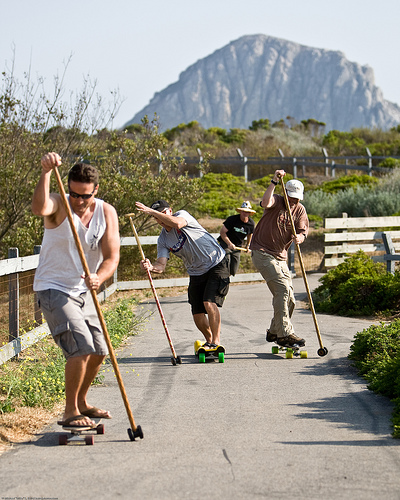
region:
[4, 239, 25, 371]
A wooden fence post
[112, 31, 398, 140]
A mountain in the background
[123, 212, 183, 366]
A wooden push pole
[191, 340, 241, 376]
A skateboard with green wheels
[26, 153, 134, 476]
A man wearing flip flops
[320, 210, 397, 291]
A wooden fence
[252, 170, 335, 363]
A man on a skateboard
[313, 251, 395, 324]
A green bush in a park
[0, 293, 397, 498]
An asphalt skating path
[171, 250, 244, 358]
A pair of brown cargo shorts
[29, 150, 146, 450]
a man skateboarding with a pole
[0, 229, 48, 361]
a small wooden fence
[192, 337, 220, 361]
a skateboard with colorful wheels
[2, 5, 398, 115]
a pristine gray sky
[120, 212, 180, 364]
a pole with wheels used to propel a skateboard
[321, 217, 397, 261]
a wooden barricade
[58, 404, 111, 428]
a man's flipflops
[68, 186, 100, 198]
a man's sunglasses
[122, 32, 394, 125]
a rocky mountain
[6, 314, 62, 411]
wild flowers growing on the dirt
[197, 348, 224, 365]
green skate board wheels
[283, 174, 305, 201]
white hat on head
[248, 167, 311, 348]
man with black watch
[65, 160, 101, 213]
sunglasses on mans face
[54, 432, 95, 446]
red skate board wheels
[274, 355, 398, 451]
shadows from green shrubs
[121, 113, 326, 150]
tall trees in background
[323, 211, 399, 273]
fence made of wood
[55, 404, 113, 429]
sandals on mans feet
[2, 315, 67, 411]
yellow flowers near path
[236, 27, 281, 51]
curved top of large mountain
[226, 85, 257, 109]
curves in large white mountain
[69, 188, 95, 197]
wrap a round sun glasses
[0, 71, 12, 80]
single leaf on branch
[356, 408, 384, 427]
indent in white sidewalk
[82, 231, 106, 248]
black logo on white tee shirt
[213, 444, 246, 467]
black spot in road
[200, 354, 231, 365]
green wheels on skateboard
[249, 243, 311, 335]
man wearing tan pants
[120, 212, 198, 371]
large stick in man's hand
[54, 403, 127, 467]
Skateboard on a paved path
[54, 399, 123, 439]
Sandals worn by a skateboarder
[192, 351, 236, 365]
Bright green wheels on a skateboard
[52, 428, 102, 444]
Red wheels on a skateboard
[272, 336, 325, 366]
Yellow wheels on a skateboard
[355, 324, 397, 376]
Bushes on the side of a paved path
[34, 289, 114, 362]
Gray shorts on a skateboarder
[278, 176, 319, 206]
White hat on a man who is skateboarding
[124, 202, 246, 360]
Man pushing himself on a skateboard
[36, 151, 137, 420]
Man wearing sunglasses on a skateboard